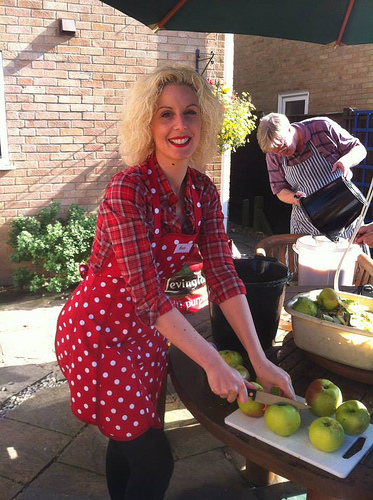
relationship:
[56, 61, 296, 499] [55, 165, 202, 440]
woman wearing apron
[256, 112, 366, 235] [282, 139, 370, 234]
man wearing apron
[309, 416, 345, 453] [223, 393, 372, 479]
apple on cutting board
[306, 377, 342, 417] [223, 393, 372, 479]
apple on cutting board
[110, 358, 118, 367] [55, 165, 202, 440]
polka dot on apron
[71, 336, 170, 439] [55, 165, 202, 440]
polka dot on apron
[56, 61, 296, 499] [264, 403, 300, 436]
woman cutting apple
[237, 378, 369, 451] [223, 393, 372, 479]
apples on cutting board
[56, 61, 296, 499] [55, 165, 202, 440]
woman has apron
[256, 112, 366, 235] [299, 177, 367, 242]
man holding bucket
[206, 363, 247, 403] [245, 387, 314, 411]
hand holding knife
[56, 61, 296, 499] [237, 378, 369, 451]
woman cutting apples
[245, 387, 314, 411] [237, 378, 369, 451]
knife cutting apples